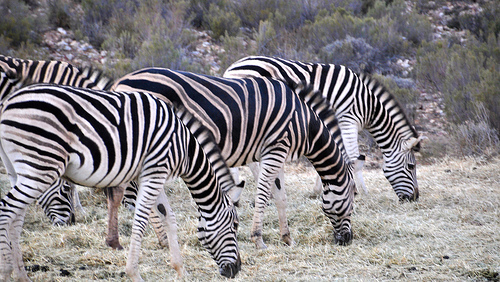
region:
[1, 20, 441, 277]
four zebras grazing in the grass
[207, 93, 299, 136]
striped pattern on zebra fur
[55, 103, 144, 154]
black and white stripes on zebra fur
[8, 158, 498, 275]
grass field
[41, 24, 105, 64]
rocks on hill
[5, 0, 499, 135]
green bushes on hill top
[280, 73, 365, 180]
black and white zebra mane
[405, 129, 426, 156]
zebra ear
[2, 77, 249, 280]
zebra eating grass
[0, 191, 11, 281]
leg of a zebra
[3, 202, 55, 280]
leg of a zebra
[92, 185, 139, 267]
leg of a zebra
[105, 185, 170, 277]
leg of a zebra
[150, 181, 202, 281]
leg of a zebra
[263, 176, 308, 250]
leg of a zebra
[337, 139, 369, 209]
leg of a zebra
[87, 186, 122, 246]
leg of a zebra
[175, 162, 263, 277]
head of a zebra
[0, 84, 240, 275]
white zebra grazing on ground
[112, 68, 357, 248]
white zebra grazing on ground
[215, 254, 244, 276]
black nose of zebra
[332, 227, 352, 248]
black nose of zebra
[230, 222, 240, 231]
black eye of zebra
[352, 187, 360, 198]
black eye of zebra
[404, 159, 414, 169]
black eye of zebra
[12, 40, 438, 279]
these are zebras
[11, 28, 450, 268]
the zebras are grazing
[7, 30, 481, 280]
the zebras are in a field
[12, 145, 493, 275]
the grass is almost white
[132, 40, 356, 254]
this zebra has some lighter tripes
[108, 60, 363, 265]
this zebra has some faded stripes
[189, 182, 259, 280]
this is the head of a zebra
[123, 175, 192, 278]
these are front legs of a zebra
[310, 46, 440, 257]
these zebras are eating grass on the ground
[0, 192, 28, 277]
leg of a zebra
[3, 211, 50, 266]
leg of a zebra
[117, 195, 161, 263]
leg of a zebra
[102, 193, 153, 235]
leg of a zebra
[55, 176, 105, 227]
leg of a zebra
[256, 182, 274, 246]
leg of a zebra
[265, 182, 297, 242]
leg of a zebra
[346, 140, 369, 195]
leg of a zebra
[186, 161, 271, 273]
head of a zebra